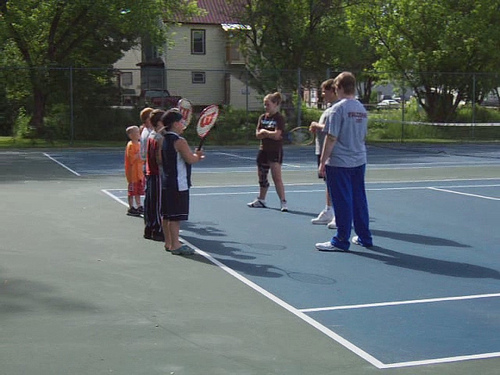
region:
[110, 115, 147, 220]
small boy wears an orange shirt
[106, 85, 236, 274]
four boys in front of three adults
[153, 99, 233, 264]
a boy holding a racket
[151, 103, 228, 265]
boy holding a blue and white tank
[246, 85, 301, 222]
a girl holding a pony tail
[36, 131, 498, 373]
tennis court is blue and green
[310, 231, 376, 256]
white tennis shoes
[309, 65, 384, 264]
woman wearing long blue pants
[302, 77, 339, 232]
person wearing blue shorts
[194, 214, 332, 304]
shadows of people cast on the ground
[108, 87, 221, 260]
four young boys on a tennis court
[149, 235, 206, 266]
young boy wearing clogs on tennis court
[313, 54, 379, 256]
person wearing blue pants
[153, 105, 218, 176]
child holding tennis racket in hands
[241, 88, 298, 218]
young girl with support braces on right leg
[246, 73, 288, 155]
girl in brown t shirt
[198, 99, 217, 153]
tennis racket has a w on it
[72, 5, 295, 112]
yellow house in the background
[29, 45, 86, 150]
fence at the edge of the tennis court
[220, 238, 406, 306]
tennis court surface is blue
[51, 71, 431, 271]
Children on the court.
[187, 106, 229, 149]
Kids holding tennis racket.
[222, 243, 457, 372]
White lines on the court.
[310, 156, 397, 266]
The person is wearing blue pants.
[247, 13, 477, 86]
The trees are next to the court.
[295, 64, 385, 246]
People standing on the tennis court.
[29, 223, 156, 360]
The court is green.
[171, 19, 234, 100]
Windows on the side of the house.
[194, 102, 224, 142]
A letter "W" on the racket.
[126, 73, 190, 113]
A truck parked in front of the house.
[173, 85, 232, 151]
boys are holding rackets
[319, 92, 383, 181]
man's shirt is gray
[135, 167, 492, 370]
tennis court is blue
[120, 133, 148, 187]
boy's shirt is orange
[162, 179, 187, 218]
boy's shorts are black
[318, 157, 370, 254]
man's pants are blue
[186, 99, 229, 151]
racket is red and black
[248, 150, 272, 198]
woman wearing brace on leg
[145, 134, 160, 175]
boy's shirt is red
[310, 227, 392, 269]
man's shoes are white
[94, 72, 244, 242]
kids learning to play tennis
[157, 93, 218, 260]
a boy holding a tennis racket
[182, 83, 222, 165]
a wilson tennis racket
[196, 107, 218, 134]
a red W on the racket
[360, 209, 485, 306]
shadows on the ground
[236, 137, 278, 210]
girl wearing a knee brace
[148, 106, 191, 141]
boy wearing a baseball hat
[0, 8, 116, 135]
the tree behind the fence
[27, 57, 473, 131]
a silver long fence